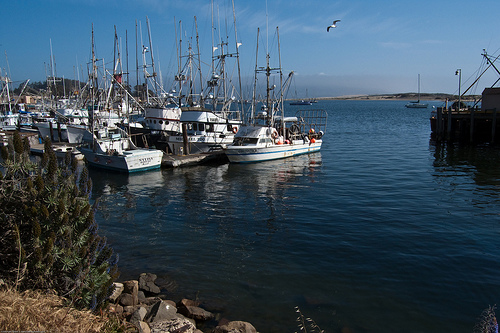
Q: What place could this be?
A: It is a harbor.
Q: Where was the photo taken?
A: It was taken at the harbor.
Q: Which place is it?
A: It is a harbor.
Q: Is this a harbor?
A: Yes, it is a harbor.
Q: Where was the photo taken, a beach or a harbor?
A: It was taken at a harbor.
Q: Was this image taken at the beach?
A: No, the picture was taken in the harbor.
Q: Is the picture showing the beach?
A: No, the picture is showing the harbor.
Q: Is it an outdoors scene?
A: Yes, it is outdoors.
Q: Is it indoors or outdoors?
A: It is outdoors.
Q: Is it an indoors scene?
A: No, it is outdoors.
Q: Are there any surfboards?
A: No, there are no surfboards.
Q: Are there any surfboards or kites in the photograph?
A: No, there are no surfboards or kites.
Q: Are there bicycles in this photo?
A: No, there are no bicycles.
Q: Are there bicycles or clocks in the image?
A: No, there are no bicycles or clocks.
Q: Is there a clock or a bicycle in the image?
A: No, there are no bicycles or clocks.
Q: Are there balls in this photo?
A: No, there are no balls.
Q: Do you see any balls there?
A: No, there are no balls.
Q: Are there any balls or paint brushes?
A: No, there are no balls or paint brushes.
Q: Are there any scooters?
A: No, there are no scooters.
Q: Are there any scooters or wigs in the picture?
A: No, there are no scooters or wigs.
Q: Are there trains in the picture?
A: Yes, there is a train.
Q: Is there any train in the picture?
A: Yes, there is a train.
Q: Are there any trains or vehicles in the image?
A: Yes, there is a train.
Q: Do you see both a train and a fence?
A: No, there is a train but no fences.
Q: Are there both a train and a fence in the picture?
A: No, there is a train but no fences.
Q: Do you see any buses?
A: No, there are no buses.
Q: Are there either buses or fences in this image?
A: No, there are no buses or fences.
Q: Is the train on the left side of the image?
A: Yes, the train is on the left of the image.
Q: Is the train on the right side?
A: No, the train is on the left of the image.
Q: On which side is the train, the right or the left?
A: The train is on the left of the image.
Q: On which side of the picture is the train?
A: The train is on the left of the image.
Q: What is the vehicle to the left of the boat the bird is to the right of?
A: The vehicle is a train.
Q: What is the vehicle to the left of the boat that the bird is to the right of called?
A: The vehicle is a train.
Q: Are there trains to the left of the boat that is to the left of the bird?
A: Yes, there is a train to the left of the boat.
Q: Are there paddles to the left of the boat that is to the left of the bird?
A: No, there is a train to the left of the boat.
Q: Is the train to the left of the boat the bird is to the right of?
A: Yes, the train is to the left of the boat.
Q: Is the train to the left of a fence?
A: No, the train is to the left of the boat.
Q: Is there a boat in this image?
A: Yes, there is a boat.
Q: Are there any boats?
A: Yes, there is a boat.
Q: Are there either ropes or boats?
A: Yes, there is a boat.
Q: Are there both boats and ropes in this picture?
A: No, there is a boat but no ropes.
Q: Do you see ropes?
A: No, there are no ropes.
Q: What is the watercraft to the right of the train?
A: The watercraft is a boat.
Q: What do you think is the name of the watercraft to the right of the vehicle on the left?
A: The watercraft is a boat.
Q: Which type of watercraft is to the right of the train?
A: The watercraft is a boat.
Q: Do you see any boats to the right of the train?
A: Yes, there is a boat to the right of the train.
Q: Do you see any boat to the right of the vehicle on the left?
A: Yes, there is a boat to the right of the train.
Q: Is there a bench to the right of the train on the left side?
A: No, there is a boat to the right of the train.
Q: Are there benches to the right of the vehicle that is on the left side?
A: No, there is a boat to the right of the train.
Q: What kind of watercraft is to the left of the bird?
A: The watercraft is a boat.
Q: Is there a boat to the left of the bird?
A: Yes, there is a boat to the left of the bird.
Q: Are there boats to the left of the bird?
A: Yes, there is a boat to the left of the bird.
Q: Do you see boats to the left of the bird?
A: Yes, there is a boat to the left of the bird.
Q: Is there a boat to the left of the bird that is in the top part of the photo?
A: Yes, there is a boat to the left of the bird.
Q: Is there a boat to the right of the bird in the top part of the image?
A: No, the boat is to the left of the bird.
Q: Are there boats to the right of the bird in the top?
A: No, the boat is to the left of the bird.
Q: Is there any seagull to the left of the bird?
A: No, there is a boat to the left of the bird.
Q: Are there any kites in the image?
A: No, there are no kites.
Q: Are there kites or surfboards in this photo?
A: No, there are no kites or surfboards.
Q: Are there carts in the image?
A: No, there are no carts.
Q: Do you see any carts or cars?
A: No, there are no carts or cars.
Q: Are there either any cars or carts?
A: No, there are no carts or cars.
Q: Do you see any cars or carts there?
A: No, there are no carts or cars.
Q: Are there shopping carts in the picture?
A: No, there are no shopping carts.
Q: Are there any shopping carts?
A: No, there are no shopping carts.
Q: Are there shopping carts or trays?
A: No, there are no shopping carts or trays.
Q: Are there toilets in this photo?
A: No, there are no toilets.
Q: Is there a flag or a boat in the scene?
A: Yes, there is a boat.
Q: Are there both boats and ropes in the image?
A: No, there is a boat but no ropes.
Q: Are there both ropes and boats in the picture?
A: No, there is a boat but no ropes.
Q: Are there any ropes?
A: No, there are no ropes.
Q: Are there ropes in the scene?
A: No, there are no ropes.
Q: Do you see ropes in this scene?
A: No, there are no ropes.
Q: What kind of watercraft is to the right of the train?
A: The watercraft is a boat.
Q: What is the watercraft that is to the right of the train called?
A: The watercraft is a boat.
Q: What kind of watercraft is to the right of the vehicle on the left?
A: The watercraft is a boat.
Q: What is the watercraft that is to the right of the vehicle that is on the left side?
A: The watercraft is a boat.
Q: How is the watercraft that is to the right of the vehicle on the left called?
A: The watercraft is a boat.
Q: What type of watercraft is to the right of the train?
A: The watercraft is a boat.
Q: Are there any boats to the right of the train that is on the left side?
A: Yes, there is a boat to the right of the train.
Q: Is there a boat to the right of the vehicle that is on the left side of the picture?
A: Yes, there is a boat to the right of the train.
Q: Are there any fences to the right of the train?
A: No, there is a boat to the right of the train.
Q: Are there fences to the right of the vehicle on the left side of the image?
A: No, there is a boat to the right of the train.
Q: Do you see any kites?
A: No, there are no kites.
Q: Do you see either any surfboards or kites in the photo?
A: No, there are no kites or surfboards.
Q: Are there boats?
A: Yes, there is a boat.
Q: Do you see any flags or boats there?
A: Yes, there is a boat.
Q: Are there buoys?
A: No, there are no buoys.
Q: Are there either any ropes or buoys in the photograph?
A: No, there are no buoys or ropes.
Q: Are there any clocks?
A: No, there are no clocks.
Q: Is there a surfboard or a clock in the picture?
A: No, there are no clocks or surfboards.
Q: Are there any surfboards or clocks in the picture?
A: No, there are no clocks or surfboards.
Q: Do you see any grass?
A: Yes, there is grass.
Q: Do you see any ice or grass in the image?
A: Yes, there is grass.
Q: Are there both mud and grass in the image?
A: No, there is grass but no mud.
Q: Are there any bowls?
A: No, there are no bowls.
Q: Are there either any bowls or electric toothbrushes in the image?
A: No, there are no bowls or electric toothbrushes.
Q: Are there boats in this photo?
A: Yes, there is a boat.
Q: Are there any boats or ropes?
A: Yes, there is a boat.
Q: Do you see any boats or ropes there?
A: Yes, there is a boat.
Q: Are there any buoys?
A: No, there are no buoys.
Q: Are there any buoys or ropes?
A: No, there are no buoys or ropes.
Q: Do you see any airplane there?
A: No, there are no airplanes.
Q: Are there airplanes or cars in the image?
A: No, there are no airplanes or cars.